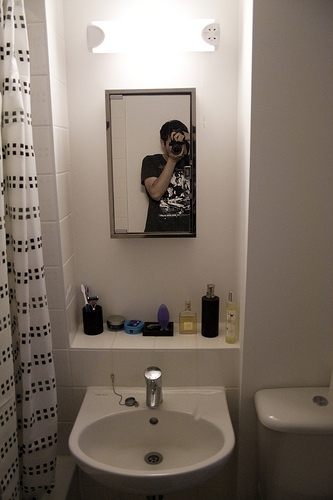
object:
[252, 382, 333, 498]
back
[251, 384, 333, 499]
toilet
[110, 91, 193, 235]
mirror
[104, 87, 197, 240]
frame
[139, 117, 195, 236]
reflection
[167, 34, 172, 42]
lights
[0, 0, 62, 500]
shower curtain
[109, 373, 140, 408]
plug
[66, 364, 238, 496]
sink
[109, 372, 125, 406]
chain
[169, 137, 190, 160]
camera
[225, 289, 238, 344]
toiletry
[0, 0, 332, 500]
bathroom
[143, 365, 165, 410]
faucet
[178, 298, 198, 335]
bottle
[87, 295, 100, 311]
shaver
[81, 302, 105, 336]
cup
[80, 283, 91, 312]
toothbrush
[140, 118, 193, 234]
man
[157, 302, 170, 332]
products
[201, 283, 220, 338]
bottles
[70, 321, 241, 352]
shelf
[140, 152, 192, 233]
shirt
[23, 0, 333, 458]
wall